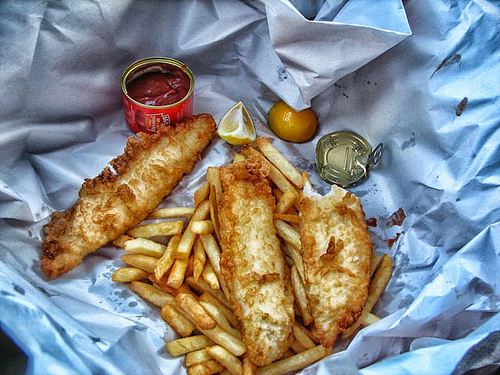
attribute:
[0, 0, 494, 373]
fabric — blue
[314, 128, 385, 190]
lid — silver, can's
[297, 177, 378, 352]
fish — broken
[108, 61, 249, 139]
can — small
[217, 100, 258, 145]
lemon — slice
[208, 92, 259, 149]
lemon — slice